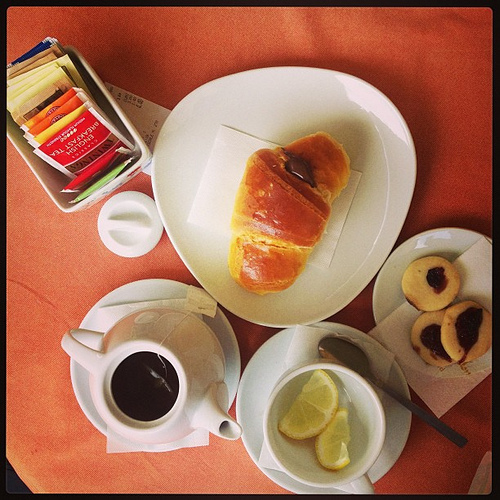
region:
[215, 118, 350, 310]
a croissant on a white plate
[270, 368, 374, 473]
a white bowl with two lemon slices inside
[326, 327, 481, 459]
a grey metal spoon on a plate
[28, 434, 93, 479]
a red table cloth on the table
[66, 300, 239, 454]
a white teapot on a plate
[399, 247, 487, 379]
three cookies topped with jam on a plate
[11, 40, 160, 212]
several tea bags in a carrier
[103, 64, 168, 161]
a receipt on the table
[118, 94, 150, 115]
black lettering on a white piece of paper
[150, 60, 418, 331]
a white off shape plate on a table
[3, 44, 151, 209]
various tea bags on the table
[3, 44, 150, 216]
white container holding several tea bag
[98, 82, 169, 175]
receipt for the food under the plate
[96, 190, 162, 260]
white lid to the tea pot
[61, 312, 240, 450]
white tea pot full of tea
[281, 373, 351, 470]
lemon slices in a cup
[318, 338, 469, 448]
metal spoon next to the cup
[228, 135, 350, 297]
chocolate fill crossant on the plate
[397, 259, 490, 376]
cookies on the small plate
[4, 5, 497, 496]
orange table with breakfast on it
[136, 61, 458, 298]
plate on the table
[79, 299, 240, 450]
teapot on the plate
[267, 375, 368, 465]
lemons in a bowl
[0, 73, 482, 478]
overhead photo of table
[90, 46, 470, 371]
many plates on the table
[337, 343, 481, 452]
utensil on the plate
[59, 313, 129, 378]
handle of the teapot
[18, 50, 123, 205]
items in a bowl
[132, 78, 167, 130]
paper under the plate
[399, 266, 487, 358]
food on the plate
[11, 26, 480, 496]
set of plates on a table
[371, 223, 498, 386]
saucer with pastries on it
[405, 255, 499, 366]
pastries on a saucer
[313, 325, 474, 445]
utensil on a saucer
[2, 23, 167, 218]
container with variety of teas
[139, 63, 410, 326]
larger saucer with pastry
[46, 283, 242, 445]
small kettle with brewed drink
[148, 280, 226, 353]
bag string for brewed drink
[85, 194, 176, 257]
top to small kettle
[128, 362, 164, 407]
brewed drink inside kettle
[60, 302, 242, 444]
a white teapot on a plate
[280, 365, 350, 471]
two slices of lemon in a cup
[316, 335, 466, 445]
a spoon on a white plate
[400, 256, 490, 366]
three cookies on a napkin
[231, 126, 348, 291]
a chocolate bread on a white plate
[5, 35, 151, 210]
tea bags in a container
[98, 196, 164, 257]
white lid of a teapot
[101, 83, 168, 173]
a bill beneath a plate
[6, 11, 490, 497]
an orange tablecloth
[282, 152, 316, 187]
melted chocolate